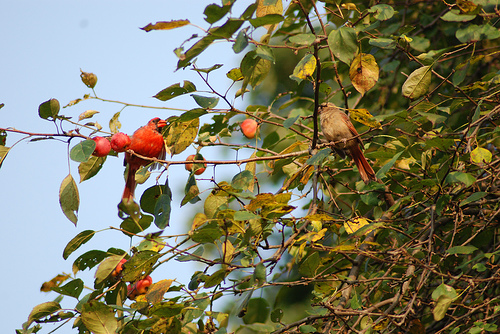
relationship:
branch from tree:
[2, 124, 368, 167] [257, 0, 500, 333]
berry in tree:
[136, 280, 149, 293] [257, 0, 500, 333]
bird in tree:
[315, 102, 379, 186] [257, 0, 500, 333]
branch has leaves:
[2, 124, 368, 167] [2, 0, 497, 331]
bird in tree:
[118, 115, 168, 201] [257, 0, 500, 333]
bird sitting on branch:
[118, 115, 168, 201] [2, 124, 368, 167]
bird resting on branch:
[118, 115, 168, 201] [2, 124, 368, 167]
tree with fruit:
[257, 0, 500, 333] [111, 131, 131, 153]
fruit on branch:
[111, 131, 131, 153] [2, 124, 368, 167]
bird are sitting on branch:
[315, 101, 377, 186] [2, 124, 368, 167]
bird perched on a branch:
[315, 101, 377, 186] [2, 124, 368, 167]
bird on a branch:
[315, 102, 379, 186] [2, 124, 368, 167]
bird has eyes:
[118, 115, 168, 201] [152, 117, 159, 124]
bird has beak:
[118, 115, 168, 201] [157, 119, 167, 127]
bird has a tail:
[315, 102, 379, 186] [347, 144, 376, 182]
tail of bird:
[347, 144, 376, 182] [315, 102, 379, 186]